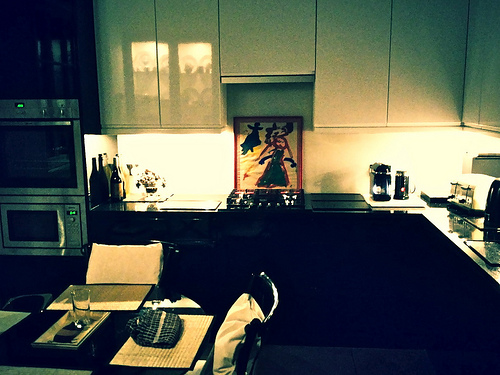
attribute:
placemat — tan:
[44, 281, 152, 313]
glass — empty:
[67, 286, 89, 324]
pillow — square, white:
[207, 283, 268, 373]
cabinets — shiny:
[93, 0, 220, 130]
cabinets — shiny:
[220, 0, 315, 77]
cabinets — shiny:
[314, 0, 465, 125]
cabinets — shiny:
[459, 3, 498, 118]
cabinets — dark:
[88, 216, 495, 373]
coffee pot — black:
[363, 156, 393, 201]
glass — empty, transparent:
[65, 281, 95, 323]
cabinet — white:
[96, 4, 156, 153]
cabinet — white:
[153, 7, 221, 127]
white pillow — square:
[89, 244, 164, 286]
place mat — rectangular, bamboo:
[108, 309, 219, 371]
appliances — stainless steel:
[8, 100, 83, 260]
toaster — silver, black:
[232, 122, 309, 194]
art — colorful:
[241, 117, 328, 192]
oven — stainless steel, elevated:
[2, 102, 87, 194]